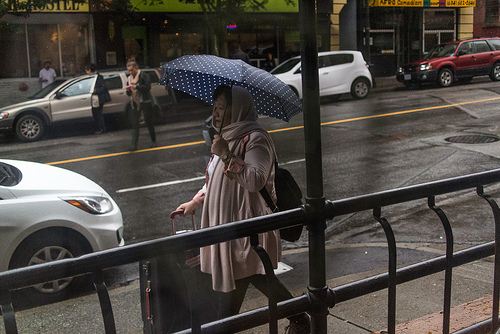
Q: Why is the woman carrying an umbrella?
A: It's raining.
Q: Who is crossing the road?
A: A woman in a gray jacket.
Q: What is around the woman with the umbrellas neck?
A: A scarf.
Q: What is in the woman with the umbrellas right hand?
A: A suitcase.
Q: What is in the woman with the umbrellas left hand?
A: An umbrella.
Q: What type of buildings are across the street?
A: Commercial.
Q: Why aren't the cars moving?
A: They're parked.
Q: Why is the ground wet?
A: It's raining.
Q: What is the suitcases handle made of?
A: Wood and metal.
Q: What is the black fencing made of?
A: Metal.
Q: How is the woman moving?
A: Walking.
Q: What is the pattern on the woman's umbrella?
A: Polka dots.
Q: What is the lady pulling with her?
A: A suitcase.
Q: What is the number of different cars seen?
A: There are four.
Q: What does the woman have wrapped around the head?
A: A scarf.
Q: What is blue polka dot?
A: Umbrella.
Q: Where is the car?
A: On the street.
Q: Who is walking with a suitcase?
A: The woman.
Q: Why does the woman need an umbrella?
A: It is raining.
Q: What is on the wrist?
A: A watch.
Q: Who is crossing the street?
A: The woman.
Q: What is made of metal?
A: Fence.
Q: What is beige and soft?
A: Sweater.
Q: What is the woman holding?
A: An umbrella.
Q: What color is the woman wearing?
A: Beige.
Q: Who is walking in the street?
A: A woman.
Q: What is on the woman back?
A: A backpack.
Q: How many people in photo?
A: Four.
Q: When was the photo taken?
A: Daytime.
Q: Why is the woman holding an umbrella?
A: Rainy day.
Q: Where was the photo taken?
A: On a city sidewalk.